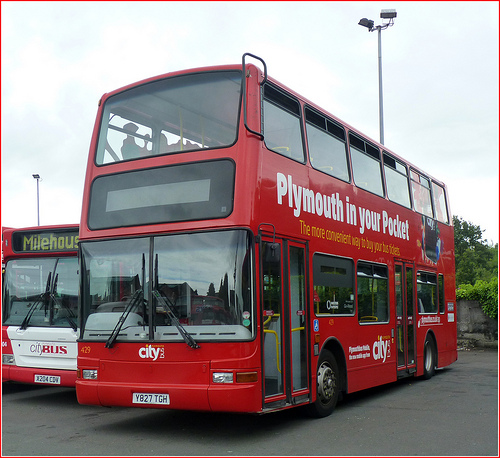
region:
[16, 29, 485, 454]
Buses are pictured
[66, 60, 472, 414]
This is a double-decker bus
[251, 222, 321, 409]
The bus's front doors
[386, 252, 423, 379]
The bus's rear doors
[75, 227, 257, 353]
This is the bus's windshield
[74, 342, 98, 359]
The bus's identification number is here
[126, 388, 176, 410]
The license plate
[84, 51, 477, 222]
This is the bus's upper deck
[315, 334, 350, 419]
This is the front wheel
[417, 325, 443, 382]
This is the rear wheel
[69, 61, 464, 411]
A double decker bus.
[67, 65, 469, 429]
The bus is tall.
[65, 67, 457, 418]
The bus is red.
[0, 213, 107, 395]
Another bus is to the left.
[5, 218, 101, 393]
The bus is red and white.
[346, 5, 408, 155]
A light pole is behind the bus.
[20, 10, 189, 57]
The sky is white.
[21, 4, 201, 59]
The sky is cloudy.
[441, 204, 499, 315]
Trees are behind the bus.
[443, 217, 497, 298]
The trees are green.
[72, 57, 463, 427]
a red double decker bus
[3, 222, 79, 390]
a red and white bus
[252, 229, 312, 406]
bus exit doors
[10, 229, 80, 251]
bus electronic destination sign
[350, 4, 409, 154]
a tall light pole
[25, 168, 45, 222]
a tall light pole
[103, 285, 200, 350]
a pair of bus windshield wipers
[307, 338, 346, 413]
a bus front left tire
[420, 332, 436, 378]
a bus left rear tire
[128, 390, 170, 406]
a bus white license plate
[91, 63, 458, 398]
red white and yellow double deck bus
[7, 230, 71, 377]
red and white bus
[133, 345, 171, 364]
white sign on red bus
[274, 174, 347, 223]
white sign on red bus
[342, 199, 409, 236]
white sign on red bus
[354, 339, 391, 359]
white sign on red bus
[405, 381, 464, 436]
gray steet pavement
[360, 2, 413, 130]
gray light pole in lot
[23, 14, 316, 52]
white clouds against blue sky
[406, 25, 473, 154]
white clouds against blue sky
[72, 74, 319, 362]
the bus is red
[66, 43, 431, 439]
the bus is red